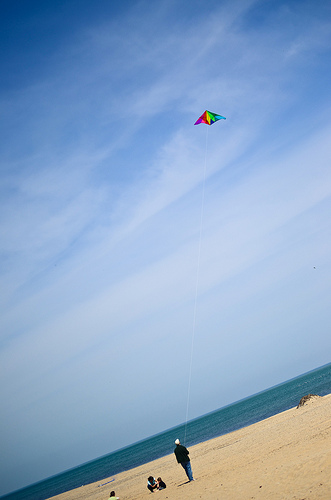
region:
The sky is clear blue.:
[12, 18, 325, 367]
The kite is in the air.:
[189, 110, 230, 134]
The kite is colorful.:
[189, 109, 230, 130]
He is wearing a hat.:
[168, 436, 184, 446]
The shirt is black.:
[170, 443, 196, 460]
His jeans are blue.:
[177, 462, 201, 482]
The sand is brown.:
[66, 427, 320, 499]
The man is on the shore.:
[6, 350, 329, 498]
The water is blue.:
[13, 366, 320, 498]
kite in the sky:
[173, 85, 250, 155]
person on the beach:
[166, 430, 198, 482]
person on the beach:
[156, 476, 169, 493]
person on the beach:
[143, 473, 155, 490]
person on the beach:
[107, 486, 120, 498]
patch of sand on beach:
[257, 465, 273, 479]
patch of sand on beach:
[215, 479, 224, 488]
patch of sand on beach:
[288, 478, 300, 490]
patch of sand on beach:
[254, 441, 266, 453]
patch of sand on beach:
[303, 424, 313, 437]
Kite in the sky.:
[180, 75, 248, 160]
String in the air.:
[123, 241, 253, 414]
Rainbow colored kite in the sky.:
[180, 85, 255, 140]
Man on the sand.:
[162, 425, 211, 494]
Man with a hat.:
[158, 425, 205, 496]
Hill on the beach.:
[275, 371, 326, 424]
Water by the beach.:
[172, 383, 249, 461]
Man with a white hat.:
[149, 434, 207, 498]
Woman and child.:
[136, 472, 166, 493]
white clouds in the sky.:
[55, 232, 175, 344]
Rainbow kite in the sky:
[183, 93, 225, 136]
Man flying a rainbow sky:
[169, 429, 195, 472]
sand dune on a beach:
[289, 390, 325, 419]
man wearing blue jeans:
[173, 460, 199, 487]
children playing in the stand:
[136, 472, 169, 498]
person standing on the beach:
[94, 485, 117, 496]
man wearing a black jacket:
[166, 448, 194, 461]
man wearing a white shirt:
[170, 437, 183, 448]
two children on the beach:
[141, 472, 173, 493]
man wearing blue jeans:
[176, 457, 200, 481]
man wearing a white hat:
[172, 437, 181, 445]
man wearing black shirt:
[169, 445, 192, 464]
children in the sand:
[134, 468, 171, 496]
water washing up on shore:
[222, 384, 300, 410]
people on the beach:
[89, 439, 224, 497]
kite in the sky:
[190, 104, 230, 137]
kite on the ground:
[86, 471, 127, 497]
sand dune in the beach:
[291, 382, 317, 408]